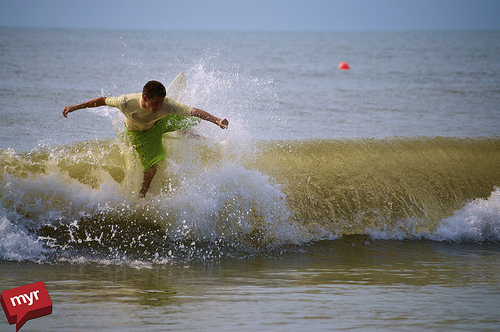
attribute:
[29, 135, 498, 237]
wave — spraying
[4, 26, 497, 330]
water — calm, splashing, wavy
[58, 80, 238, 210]
man — reflecting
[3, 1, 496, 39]
sky — blue, clear